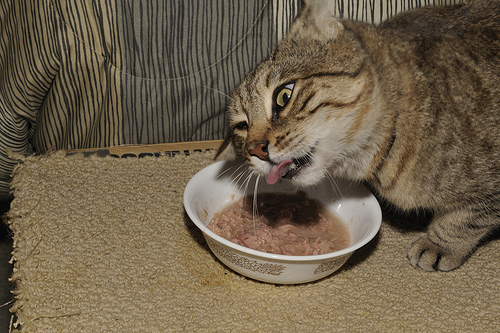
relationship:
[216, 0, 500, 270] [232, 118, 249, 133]
cat has a right eye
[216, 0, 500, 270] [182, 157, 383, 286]
cat in front of its meal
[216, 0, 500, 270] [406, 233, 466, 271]
cat has a paw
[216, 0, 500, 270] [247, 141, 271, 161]
cat has a nose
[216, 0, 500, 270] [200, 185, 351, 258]
cat in front of food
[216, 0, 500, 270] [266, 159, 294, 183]
cat has a tongue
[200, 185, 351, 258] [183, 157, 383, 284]
food in bowl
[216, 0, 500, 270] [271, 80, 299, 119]
cat has a left eye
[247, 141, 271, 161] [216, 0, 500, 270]
nose on cat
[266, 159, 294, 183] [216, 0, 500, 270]
tongue sticking out from cat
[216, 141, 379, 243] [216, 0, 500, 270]
whiskers on cat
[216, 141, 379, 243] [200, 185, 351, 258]
whiskers above food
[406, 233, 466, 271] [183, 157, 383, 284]
paw near bowl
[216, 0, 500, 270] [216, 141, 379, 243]
cat has whiskers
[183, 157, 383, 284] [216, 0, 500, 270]
bowl near cat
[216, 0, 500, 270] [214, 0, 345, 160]
cat has ears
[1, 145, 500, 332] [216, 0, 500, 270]
rug under cat